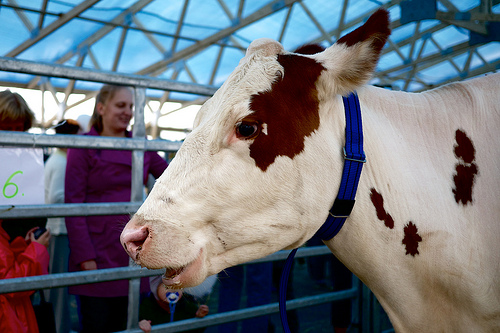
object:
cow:
[119, 8, 499, 333]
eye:
[236, 120, 258, 138]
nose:
[120, 223, 152, 261]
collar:
[312, 90, 366, 240]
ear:
[324, 9, 389, 85]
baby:
[138, 276, 208, 333]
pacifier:
[166, 291, 179, 303]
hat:
[149, 276, 163, 301]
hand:
[196, 304, 209, 317]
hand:
[139, 319, 152, 331]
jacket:
[138, 292, 202, 332]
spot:
[401, 221, 422, 257]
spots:
[452, 129, 478, 207]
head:
[118, 8, 390, 288]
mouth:
[137, 244, 206, 284]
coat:
[0, 223, 49, 333]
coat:
[63, 124, 168, 297]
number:
[1, 170, 24, 200]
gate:
[0, 57, 391, 333]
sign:
[0, 147, 45, 205]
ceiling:
[0, 0, 500, 103]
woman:
[64, 84, 169, 333]